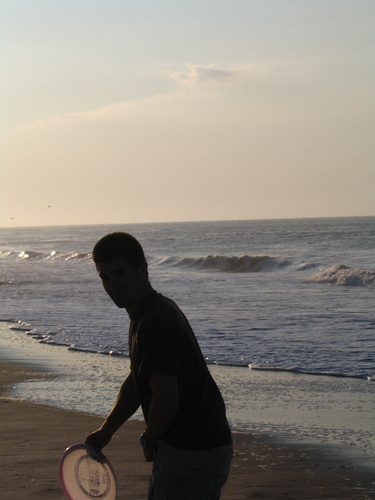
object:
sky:
[0, 0, 375, 228]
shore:
[0, 321, 374, 500]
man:
[83, 229, 235, 500]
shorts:
[144, 439, 234, 500]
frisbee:
[58, 442, 118, 500]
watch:
[139, 430, 157, 449]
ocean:
[0, 214, 374, 381]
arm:
[136, 307, 181, 440]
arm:
[102, 367, 142, 439]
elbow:
[149, 392, 180, 413]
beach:
[0, 322, 375, 500]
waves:
[0, 317, 375, 383]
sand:
[221, 428, 375, 500]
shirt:
[125, 288, 234, 452]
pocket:
[154, 461, 176, 490]